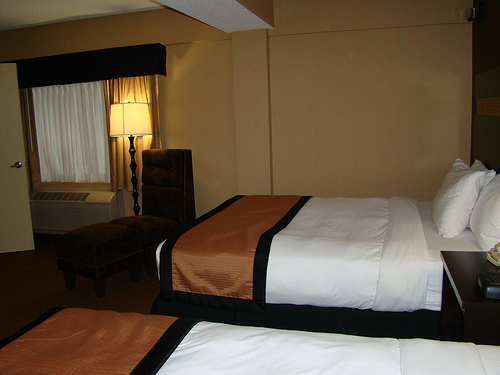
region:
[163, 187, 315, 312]
A black and gold runner at the foot of the bed.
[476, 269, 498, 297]
A black alarm clock.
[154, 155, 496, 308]
White sheets and pillowcases.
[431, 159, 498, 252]
White pillows at the top of the bed.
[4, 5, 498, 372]
A hotel room.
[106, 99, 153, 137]
A white lampshade.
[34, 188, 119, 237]
A white heater and air conditioner.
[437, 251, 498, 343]
A brown nightstand.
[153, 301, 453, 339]
A black bedskirt.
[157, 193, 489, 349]
A bed.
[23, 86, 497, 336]
two beds ina room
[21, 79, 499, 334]
a bed that is made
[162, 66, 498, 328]
a bed with three pillows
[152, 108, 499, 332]
a white bed set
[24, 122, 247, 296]
a chair in front of a bed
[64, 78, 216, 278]
a lamp turned on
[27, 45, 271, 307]
a lamp next to chair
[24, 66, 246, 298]
a chair next to lamp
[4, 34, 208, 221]
a window with curtains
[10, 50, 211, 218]
curtains on a window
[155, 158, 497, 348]
This is a bed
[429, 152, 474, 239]
This is a pillor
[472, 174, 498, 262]
This is a pillor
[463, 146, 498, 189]
This is a pillor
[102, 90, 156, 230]
This is a lamp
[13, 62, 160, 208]
This is a window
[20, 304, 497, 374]
This is a bed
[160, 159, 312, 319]
This is a bed cover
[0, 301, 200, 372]
This is a bed cover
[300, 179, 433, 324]
This is a bed sheet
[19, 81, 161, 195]
a set of closed curtains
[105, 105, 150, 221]
a tall lamp turned on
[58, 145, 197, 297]
an elongated lounge chair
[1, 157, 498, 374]
two beds with white sheets and bronze and black trimmed foot blanket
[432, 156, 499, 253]
a set of pillows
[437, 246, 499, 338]
a dark brown end table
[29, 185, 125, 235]
a hotel heating and cooling unit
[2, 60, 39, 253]
an open door with silver handle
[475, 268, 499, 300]
an alarm clock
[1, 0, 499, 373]
a hotel room with two beds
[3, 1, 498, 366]
Neat bedroom.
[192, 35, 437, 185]
Tan colored wall.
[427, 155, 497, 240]
Three standing white pillows.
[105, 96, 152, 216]
Tall lit standing lamp.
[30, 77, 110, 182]
White window curtain.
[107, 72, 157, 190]
Yellow window curtain.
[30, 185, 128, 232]
Beige wall radiator.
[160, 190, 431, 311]
White bed covered with an orange comforter accent.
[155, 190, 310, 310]
Comforter accent with brown stripe.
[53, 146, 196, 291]
Comfortable brown bedroom chair.